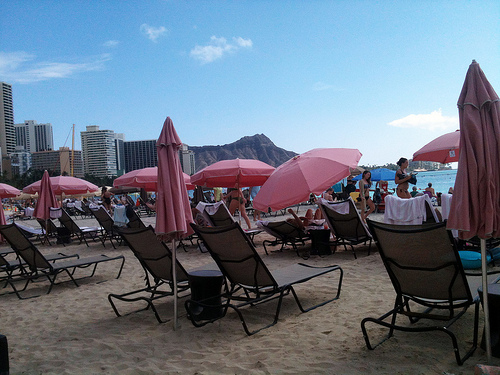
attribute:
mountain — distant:
[193, 120, 280, 158]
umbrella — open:
[246, 140, 357, 211]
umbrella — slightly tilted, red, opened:
[251, 147, 363, 214]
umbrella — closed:
[151, 117, 188, 337]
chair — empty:
[358, 211, 492, 364]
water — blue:
[349, 169, 463, 189]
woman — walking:
[353, 167, 374, 215]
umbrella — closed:
[33, 170, 56, 234]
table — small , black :
[176, 260, 239, 334]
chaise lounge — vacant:
[359, 211, 487, 366]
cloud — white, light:
[185, 43, 233, 66]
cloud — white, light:
[204, 34, 227, 46]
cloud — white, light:
[232, 36, 254, 49]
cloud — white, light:
[137, 21, 169, 45]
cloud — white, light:
[102, 39, 122, 47]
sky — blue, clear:
[2, 2, 483, 167]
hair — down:
[359, 164, 379, 191]